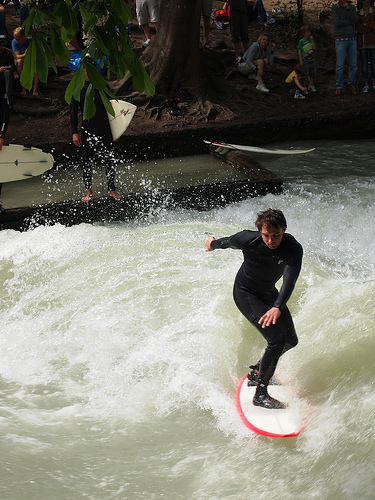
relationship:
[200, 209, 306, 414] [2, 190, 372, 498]
man surfing on wave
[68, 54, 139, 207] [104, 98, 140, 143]
person holding surfboard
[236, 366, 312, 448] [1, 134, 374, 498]
surfboard floating in water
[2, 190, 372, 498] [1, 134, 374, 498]
wave inside of water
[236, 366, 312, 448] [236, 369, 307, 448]
surfboard has edge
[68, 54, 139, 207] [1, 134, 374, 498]
person waiting beside water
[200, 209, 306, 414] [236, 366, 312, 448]
man on top of surfboard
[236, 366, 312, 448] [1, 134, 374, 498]
surfboard inside of water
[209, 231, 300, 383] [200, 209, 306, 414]
wet suit worn on man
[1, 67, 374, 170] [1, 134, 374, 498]
ground near water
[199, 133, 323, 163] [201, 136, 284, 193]
board on top of log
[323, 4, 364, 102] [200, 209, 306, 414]
spectator observing man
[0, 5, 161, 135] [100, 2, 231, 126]
branch hanging from trunk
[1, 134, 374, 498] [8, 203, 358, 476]
water splashed sea